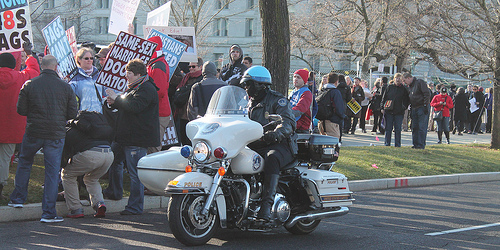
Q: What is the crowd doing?
A: Protesting.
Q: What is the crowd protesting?
A: Homosexuality.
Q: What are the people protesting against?
A: Anti gay marriage.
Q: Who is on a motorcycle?
A: A police officer.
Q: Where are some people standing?
A: Under a leafless tree.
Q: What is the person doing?
A: Standing on the pavement next to a motorcycle.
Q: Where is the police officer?
A: On a white motorcycle.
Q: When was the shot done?
A: Daytime.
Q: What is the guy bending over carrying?
A: Backpack.